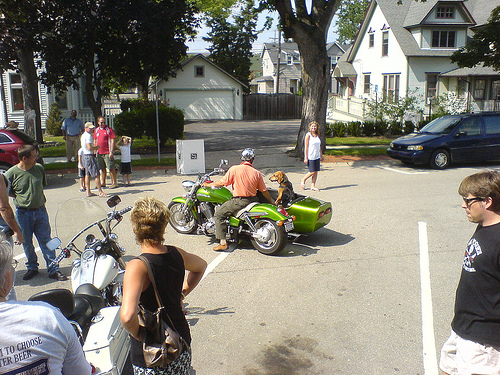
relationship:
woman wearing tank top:
[299, 115, 331, 191] [304, 133, 326, 160]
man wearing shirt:
[439, 166, 499, 374] [447, 223, 499, 348]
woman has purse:
[118, 202, 209, 371] [126, 254, 186, 367]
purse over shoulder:
[126, 254, 186, 367] [125, 251, 157, 297]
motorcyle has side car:
[166, 161, 333, 255] [259, 179, 333, 234]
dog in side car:
[270, 168, 297, 206] [259, 179, 333, 234]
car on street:
[0, 123, 45, 182] [1, 159, 498, 375]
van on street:
[382, 94, 500, 168] [1, 159, 498, 375]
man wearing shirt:
[96, 115, 119, 185] [95, 127, 113, 154]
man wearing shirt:
[6, 144, 60, 282] [4, 165, 52, 209]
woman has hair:
[118, 202, 209, 371] [132, 197, 171, 246]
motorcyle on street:
[166, 161, 333, 255] [1, 159, 498, 375]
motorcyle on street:
[46, 195, 138, 372] [1, 159, 498, 375]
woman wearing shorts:
[299, 115, 331, 191] [307, 155, 324, 172]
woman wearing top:
[118, 202, 209, 371] [127, 244, 187, 367]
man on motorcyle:
[214, 151, 274, 257] [166, 161, 333, 255]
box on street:
[170, 132, 216, 183] [1, 159, 498, 375]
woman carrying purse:
[118, 202, 209, 371] [126, 254, 186, 367]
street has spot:
[1, 159, 498, 375] [239, 320, 342, 372]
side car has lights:
[259, 179, 333, 234] [315, 203, 335, 219]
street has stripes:
[1, 159, 498, 375] [189, 208, 445, 374]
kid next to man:
[115, 129, 140, 183] [96, 115, 119, 185]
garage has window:
[150, 45, 251, 123] [190, 59, 207, 79]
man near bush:
[96, 115, 119, 185] [111, 106, 147, 140]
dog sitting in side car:
[270, 168, 297, 206] [259, 179, 333, 234]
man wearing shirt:
[214, 151, 274, 257] [220, 161, 266, 201]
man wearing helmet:
[214, 151, 274, 257] [239, 146, 258, 162]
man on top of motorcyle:
[214, 151, 274, 257] [166, 161, 333, 255]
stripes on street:
[189, 208, 445, 374] [1, 159, 498, 375]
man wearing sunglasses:
[439, 166, 499, 374] [460, 192, 484, 208]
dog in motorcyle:
[270, 168, 297, 206] [166, 161, 333, 255]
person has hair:
[1, 234, 98, 374] [1, 237, 14, 277]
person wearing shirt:
[1, 234, 98, 374] [2, 299, 94, 374]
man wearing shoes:
[214, 151, 274, 257] [215, 239, 231, 254]